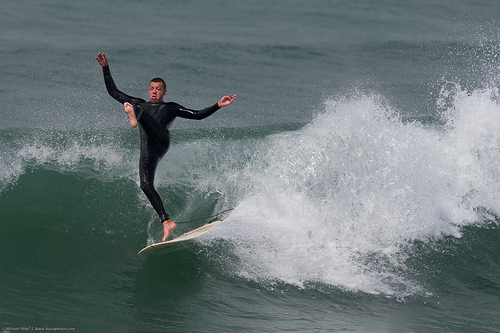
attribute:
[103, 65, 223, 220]
wetsuit — one piece, black, blac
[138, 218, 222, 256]
surfboard — white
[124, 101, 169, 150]
leg — mid air, up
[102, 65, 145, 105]
arm — outstrecthed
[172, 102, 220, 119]
arm — outstrecthed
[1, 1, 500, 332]
water — calm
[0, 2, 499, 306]
wave — strong, splash, breaking, small, spraying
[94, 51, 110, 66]
hand —  right, up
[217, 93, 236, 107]
hand —  left, up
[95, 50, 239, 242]
man — standing, surfing, light skinned, shoeless